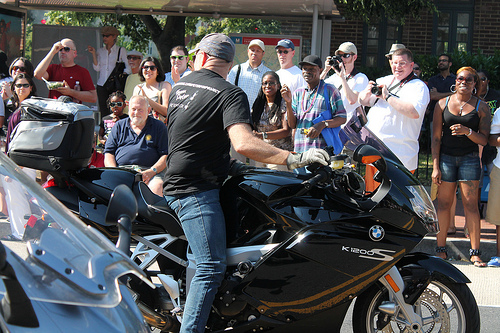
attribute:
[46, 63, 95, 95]
shirt — red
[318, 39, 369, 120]
man — taking pictures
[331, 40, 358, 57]
hat — white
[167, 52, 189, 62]
sunglasses — lime green color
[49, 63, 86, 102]
shirt — red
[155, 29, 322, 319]
man — baseball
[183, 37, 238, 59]
cap — blue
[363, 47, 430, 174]
man — smiling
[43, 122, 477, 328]
motorcycle — black, BMW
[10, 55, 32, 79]
woman — standing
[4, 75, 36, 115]
woman — standing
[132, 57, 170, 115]
woman — standing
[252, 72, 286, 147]
woman — standing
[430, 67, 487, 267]
woman — standing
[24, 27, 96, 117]
shirt — red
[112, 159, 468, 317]
motorcycle — black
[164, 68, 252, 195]
shirt — black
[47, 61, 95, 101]
shirt — maroon, red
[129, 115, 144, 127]
beard — white